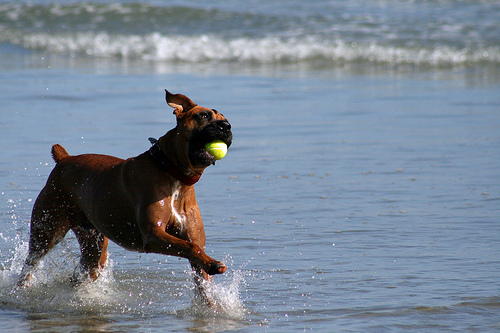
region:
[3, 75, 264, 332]
The dog is brown.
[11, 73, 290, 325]
The dog is running.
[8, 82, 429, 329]
The dog is in the water.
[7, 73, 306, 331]
The dog is wet.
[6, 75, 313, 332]
The dog is shorthaired.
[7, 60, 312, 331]
The dog has a ball in its mouth.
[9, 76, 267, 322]
The ball is yellow.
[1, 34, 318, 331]
The dog is splashing water.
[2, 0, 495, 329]
The water is shallow where the dog is.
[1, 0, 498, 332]
The water is mild.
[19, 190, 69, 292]
the brown wet leg of the dog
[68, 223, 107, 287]
the brown wet leg of the dog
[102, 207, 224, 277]
the brown wet leg of the dog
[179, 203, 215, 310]
the brown wet leg of the dog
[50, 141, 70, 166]
the brown wet tail of the dog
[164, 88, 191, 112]
the brown wet ear of the dog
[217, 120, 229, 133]
the black nose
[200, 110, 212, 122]
the brown eye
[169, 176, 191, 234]
the white spot on the chest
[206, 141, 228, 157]
the bright yellow tennis ball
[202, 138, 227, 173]
a green and white tennis ball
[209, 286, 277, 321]
water splashing up and out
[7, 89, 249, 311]
a dog running with a ball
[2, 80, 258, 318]
a dog running in the water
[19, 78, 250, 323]
a dog running in water with a ball in his mouth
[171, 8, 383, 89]
waves lapping against the water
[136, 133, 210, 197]
a red collar on a dog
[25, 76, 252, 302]
a brown dog with a white stripe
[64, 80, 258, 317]
a brown dog with a white mouth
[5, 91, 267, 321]
a dog with a small tail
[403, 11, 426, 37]
Small patch of ocean water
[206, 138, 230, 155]
Green and white tennis ball in dog's mouth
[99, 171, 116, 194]
Brown skin of dog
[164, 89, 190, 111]
Right ear of dog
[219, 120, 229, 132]
Black nose of dog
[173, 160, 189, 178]
Red neckchain on dog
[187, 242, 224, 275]
Right foot of the dog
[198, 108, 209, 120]
Right eye of the dog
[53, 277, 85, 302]
Splashes in the water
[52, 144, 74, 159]
Brown tail of dog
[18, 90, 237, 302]
the dog is running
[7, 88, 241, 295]
the dog is in the water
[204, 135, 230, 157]
the dog caught the ball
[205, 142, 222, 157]
the dog has yellow ball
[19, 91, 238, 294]
the dog is brown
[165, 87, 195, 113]
the dog has a pointy ear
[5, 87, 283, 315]
the dog splatters the water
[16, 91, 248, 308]
the dog is playing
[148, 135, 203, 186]
the dog has a collar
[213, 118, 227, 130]
the dog has black nose